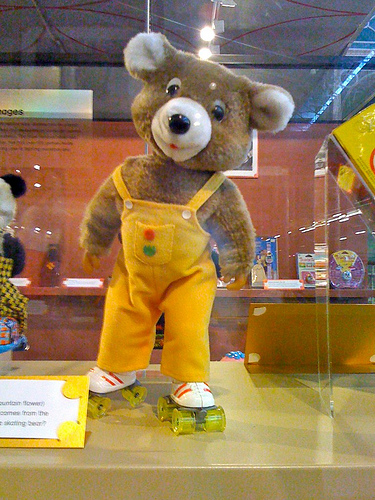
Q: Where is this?
A: This is at the display.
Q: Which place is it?
A: It is a display.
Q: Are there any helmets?
A: No, there are no helmets.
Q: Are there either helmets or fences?
A: No, there are no helmets or fences.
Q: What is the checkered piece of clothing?
A: The clothing item is an outfit.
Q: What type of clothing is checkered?
A: The clothing is an outfit.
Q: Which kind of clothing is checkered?
A: The clothing is an outfit.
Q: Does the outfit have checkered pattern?
A: Yes, the outfit is checkered.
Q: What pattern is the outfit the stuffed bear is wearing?
A: The outfit is checkered.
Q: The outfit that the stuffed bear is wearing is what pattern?
A: The outfit is checkered.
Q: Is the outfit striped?
A: No, the outfit is checkered.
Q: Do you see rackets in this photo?
A: No, there are no rackets.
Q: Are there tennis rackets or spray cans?
A: No, there are no tennis rackets or spray cans.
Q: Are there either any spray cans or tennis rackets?
A: No, there are no tennis rackets or spray cans.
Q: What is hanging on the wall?
A: The picture is hanging on the wall.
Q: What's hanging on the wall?
A: The picture is hanging on the wall.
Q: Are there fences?
A: No, there are no fences.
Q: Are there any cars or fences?
A: No, there are no fences or cars.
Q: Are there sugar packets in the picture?
A: No, there are no sugar packets.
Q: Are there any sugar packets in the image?
A: No, there are no sugar packets.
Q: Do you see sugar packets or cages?
A: No, there are no sugar packets or cages.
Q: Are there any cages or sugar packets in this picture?
A: No, there are no sugar packets or cages.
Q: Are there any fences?
A: No, there are no fences.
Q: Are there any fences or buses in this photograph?
A: No, there are no fences or buses.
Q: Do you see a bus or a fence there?
A: No, there are no fences or buses.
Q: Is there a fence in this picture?
A: No, there are no fences.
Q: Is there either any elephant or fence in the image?
A: No, there are no fences or elephants.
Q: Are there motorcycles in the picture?
A: No, there are no motorcycles.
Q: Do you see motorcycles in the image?
A: No, there are no motorcycles.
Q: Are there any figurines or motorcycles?
A: No, there are no motorcycles or figurines.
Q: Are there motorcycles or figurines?
A: No, there are no motorcycles or figurines.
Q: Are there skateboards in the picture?
A: No, there are no skateboards.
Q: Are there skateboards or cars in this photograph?
A: No, there are no skateboards or cars.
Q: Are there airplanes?
A: No, there are no airplanes.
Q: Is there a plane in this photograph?
A: No, there are no airplanes.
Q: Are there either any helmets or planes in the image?
A: No, there are no planes or helmets.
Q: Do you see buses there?
A: No, there are no buses.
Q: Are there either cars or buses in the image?
A: No, there are no buses or cars.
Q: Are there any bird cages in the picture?
A: No, there are no bird cages.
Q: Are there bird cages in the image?
A: No, there are no bird cages.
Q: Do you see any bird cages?
A: No, there are no bird cages.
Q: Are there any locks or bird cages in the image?
A: No, there are no bird cages or locks.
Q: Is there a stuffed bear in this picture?
A: Yes, there is a stuffed bear.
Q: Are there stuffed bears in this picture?
A: Yes, there is a stuffed bear.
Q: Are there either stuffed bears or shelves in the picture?
A: Yes, there is a stuffed bear.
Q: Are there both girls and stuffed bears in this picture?
A: No, there is a stuffed bear but no girls.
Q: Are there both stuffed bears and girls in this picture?
A: No, there is a stuffed bear but no girls.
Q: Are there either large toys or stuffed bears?
A: Yes, there is a large stuffed bear.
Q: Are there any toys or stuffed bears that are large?
A: Yes, the stuffed bear is large.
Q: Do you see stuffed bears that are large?
A: Yes, there is a large stuffed bear.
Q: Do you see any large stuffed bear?
A: Yes, there is a large stuffed bear.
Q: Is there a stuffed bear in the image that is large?
A: Yes, there is a stuffed bear that is large.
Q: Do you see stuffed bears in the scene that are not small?
A: Yes, there is a large stuffed bear.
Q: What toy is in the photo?
A: The toy is a stuffed bear.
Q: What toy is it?
A: The toy is a stuffed bear.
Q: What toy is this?
A: This is a stuffed bear.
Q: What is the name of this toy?
A: This is a stuffed bear.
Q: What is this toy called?
A: This is a stuffed bear.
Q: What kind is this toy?
A: This is a stuffed bear.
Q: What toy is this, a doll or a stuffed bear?
A: This is a stuffed bear.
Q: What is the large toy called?
A: The toy is a stuffed bear.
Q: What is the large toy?
A: The toy is a stuffed bear.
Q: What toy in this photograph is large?
A: The toy is a stuffed bear.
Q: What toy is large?
A: The toy is a stuffed bear.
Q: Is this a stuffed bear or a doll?
A: This is a stuffed bear.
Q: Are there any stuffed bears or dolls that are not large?
A: No, there is a stuffed bear but it is large.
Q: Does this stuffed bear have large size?
A: Yes, the stuffed bear is large.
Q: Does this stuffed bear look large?
A: Yes, the stuffed bear is large.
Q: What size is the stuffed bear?
A: The stuffed bear is large.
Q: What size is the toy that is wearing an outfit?
A: The stuffed bear is large.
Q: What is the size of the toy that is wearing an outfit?
A: The stuffed bear is large.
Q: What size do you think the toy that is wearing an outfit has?
A: The stuffed bear has large size.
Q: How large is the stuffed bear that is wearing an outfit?
A: The stuffed bear is large.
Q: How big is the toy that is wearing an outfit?
A: The stuffed bear is large.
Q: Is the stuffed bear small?
A: No, the stuffed bear is large.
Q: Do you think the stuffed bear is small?
A: No, the stuffed bear is large.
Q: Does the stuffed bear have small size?
A: No, the stuffed bear is large.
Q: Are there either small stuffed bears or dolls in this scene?
A: No, there is a stuffed bear but it is large.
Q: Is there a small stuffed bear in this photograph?
A: No, there is a stuffed bear but it is large.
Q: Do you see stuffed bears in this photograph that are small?
A: No, there is a stuffed bear but it is large.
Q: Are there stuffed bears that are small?
A: No, there is a stuffed bear but it is large.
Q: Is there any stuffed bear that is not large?
A: No, there is a stuffed bear but it is large.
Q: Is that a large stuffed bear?
A: Yes, that is a large stuffed bear.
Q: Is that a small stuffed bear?
A: No, that is a large stuffed bear.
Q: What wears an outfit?
A: The stuffed bear wears an outfit.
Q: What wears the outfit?
A: The stuffed bear wears an outfit.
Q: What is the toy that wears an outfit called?
A: The toy is a stuffed bear.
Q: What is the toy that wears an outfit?
A: The toy is a stuffed bear.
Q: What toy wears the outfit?
A: The toy is a stuffed bear.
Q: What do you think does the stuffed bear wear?
A: The stuffed bear wears an outfit.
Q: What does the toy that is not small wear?
A: The stuffed bear wears an outfit.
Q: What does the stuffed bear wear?
A: The stuffed bear wears an outfit.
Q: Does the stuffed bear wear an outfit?
A: Yes, the stuffed bear wears an outfit.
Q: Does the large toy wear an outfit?
A: Yes, the stuffed bear wears an outfit.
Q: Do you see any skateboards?
A: No, there are no skateboards.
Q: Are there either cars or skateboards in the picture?
A: No, there are no skateboards or cars.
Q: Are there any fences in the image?
A: No, there are no fences.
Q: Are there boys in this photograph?
A: No, there are no boys.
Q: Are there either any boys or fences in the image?
A: No, there are no boys or fences.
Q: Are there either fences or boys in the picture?
A: No, there are no boys or fences.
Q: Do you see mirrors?
A: No, there are no mirrors.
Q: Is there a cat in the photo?
A: No, there are no cats.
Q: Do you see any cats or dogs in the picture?
A: No, there are no cats or dogs.